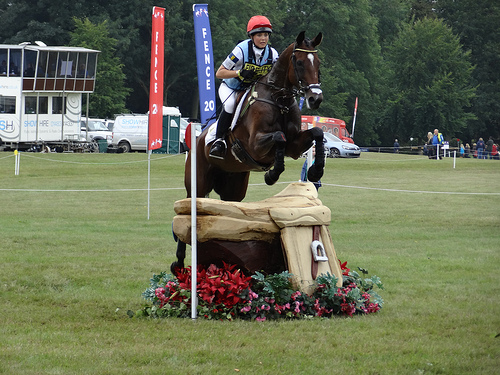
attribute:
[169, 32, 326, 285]
horse — brown, jumping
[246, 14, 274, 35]
helmet — red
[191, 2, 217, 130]
sign — blue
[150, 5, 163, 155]
sign — red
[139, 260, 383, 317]
flowers — red, pink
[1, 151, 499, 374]
grass — green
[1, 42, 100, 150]
building — white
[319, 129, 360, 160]
car — white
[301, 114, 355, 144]
suv — red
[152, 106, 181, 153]
potty — green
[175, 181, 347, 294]
complex — rock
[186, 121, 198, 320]
pole — white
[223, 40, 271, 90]
vest — blue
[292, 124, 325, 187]
leg — up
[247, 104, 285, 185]
leg — up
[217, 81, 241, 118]
pants — white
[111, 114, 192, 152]
van — white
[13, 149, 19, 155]
flag — yellow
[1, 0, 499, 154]
trees — large